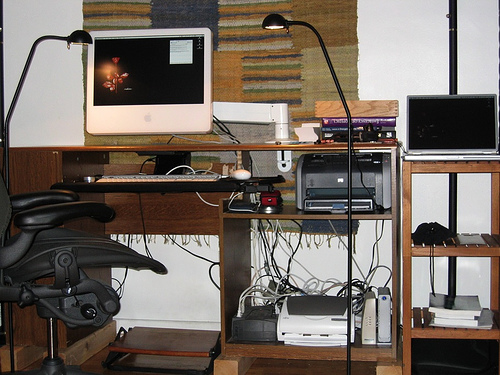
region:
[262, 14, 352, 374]
A long, black lamp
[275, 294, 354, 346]
A printing machine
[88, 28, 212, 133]
A computer monitor turned on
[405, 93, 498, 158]
A laptop on a shelf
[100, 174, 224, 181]
Keyboard that goes to a computer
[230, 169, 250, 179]
A white computer mouse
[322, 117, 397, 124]
A purple book on a desk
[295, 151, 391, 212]
A fax and printer combo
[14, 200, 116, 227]
The arm of a chair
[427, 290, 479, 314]
A manual book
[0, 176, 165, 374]
the chair in front of the desk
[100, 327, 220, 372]
the foot rest under the desk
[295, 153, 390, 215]
the printer on the shelf in the desk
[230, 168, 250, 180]
the mouse on the desk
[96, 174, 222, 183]
the keyboard on the desk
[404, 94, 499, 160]
the opened laptop on the table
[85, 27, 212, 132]
the apple imac on the desk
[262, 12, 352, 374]
the black lamp next to the desk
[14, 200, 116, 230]
the arm rest on the chair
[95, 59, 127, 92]
the glare from the light on the imac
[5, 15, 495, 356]
A home office inside somebody's house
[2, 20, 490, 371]
The room has many electronic devices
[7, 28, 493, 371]
The room has an office chair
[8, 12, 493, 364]
The room has a computer keyboard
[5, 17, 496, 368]
The room has a nice desk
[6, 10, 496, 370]
The room is inside somebody's home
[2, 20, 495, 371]
The room is the office of a student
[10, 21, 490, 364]
The room is a place for work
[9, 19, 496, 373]
The room is very well lighted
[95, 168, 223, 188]
A white computer keyboard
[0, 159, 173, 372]
A black office chair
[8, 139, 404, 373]
A brown wooden desk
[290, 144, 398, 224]
A printer on a shelf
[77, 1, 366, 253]
A rug hanging on the wall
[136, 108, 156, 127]
Button on computer monitor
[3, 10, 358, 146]
Two black office lights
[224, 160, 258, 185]
A white computer mouse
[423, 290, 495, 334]
Books on a shelf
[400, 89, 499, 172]
A laptop on a table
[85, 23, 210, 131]
A white computer monitor.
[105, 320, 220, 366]
A foot rest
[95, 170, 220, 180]
A white keyboard.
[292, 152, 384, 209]
A grey and black printer.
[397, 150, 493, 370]
A small square table with shelves.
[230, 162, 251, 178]
A white computer mouse.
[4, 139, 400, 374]
A wooden computer desk.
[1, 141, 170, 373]
A black desk chair.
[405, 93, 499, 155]
A computer screen.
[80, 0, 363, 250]
A rug hanging on the wall.